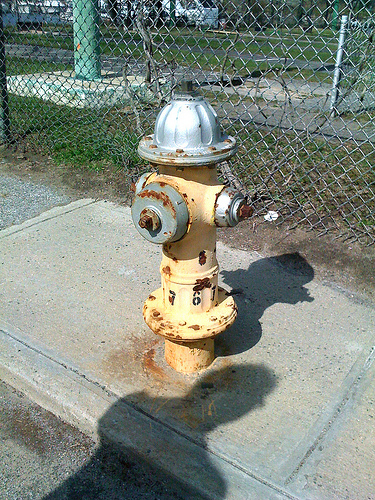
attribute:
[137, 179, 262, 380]
fire hydrant — silver, yellow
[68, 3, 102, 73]
metal pole — green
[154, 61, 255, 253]
hydrant — small, yellow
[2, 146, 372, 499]
concrete — rusty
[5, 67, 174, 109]
base — concrete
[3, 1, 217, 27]
building — small, white, distant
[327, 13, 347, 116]
post — metallic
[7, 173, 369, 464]
sidewalk — concrete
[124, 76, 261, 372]
fire hydrant — rusty, old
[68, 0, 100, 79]
pole — green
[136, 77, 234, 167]
top — silver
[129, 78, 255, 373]
hydrant — rusty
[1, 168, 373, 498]
sidewalk — rusty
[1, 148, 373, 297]
dirt — brown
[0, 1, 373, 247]
chainlink fence — tall, metal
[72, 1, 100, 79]
post — large, green